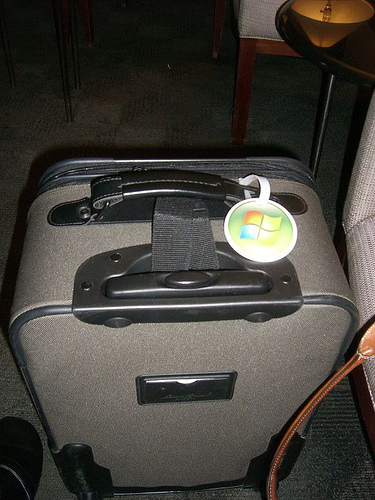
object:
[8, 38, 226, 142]
carpet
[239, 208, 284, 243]
windows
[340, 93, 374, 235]
arm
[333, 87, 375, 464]
sofa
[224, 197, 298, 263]
tag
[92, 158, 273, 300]
handles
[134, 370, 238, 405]
slot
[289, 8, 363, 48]
lamp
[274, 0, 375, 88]
table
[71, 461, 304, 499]
wheels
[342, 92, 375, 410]
cloth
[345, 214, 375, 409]
seat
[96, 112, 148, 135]
carpet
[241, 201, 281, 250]
symbol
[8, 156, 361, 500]
suitcase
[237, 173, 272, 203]
clip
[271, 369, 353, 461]
strap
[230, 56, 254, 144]
leg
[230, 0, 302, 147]
chair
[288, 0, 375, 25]
lamp shade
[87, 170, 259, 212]
suitcase handle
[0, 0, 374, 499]
carpet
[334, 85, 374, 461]
chair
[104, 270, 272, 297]
pull handle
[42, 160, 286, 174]
zipper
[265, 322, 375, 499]
purse handle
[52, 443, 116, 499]
wheel housing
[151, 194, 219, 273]
shoulder strap